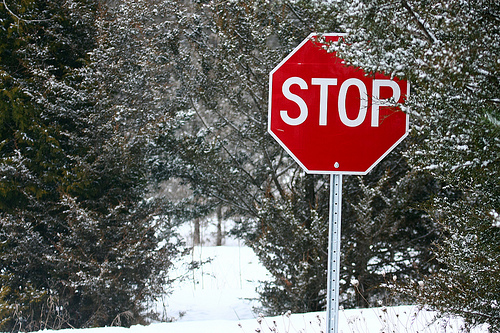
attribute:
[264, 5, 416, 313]
sign — metallic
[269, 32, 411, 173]
street sign — white, red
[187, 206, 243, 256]
trunk — light brown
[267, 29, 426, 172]
stop sign — red, white, octagonal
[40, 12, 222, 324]
snow — white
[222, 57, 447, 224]
sign — red, white, a stop sign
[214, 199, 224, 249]
trunk — light brown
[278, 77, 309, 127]
letter s — white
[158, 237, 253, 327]
pathway — snowy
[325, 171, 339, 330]
pole — metal